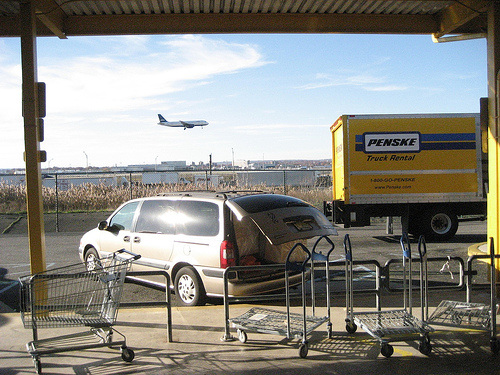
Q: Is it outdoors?
A: Yes, it is outdoors.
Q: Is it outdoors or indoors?
A: It is outdoors.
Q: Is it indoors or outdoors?
A: It is outdoors.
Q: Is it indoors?
A: No, it is outdoors.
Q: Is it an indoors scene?
A: No, it is outdoors.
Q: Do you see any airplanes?
A: Yes, there is an airplane.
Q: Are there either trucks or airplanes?
A: Yes, there is an airplane.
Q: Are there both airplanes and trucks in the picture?
A: Yes, there are both an airplane and a truck.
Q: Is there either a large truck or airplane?
A: Yes, there is a large airplane.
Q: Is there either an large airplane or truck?
A: Yes, there is a large airplane.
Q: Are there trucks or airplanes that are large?
A: Yes, the airplane is large.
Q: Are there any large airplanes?
A: Yes, there is a large airplane.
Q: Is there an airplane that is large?
A: Yes, there is an airplane that is large.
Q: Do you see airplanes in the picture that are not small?
A: Yes, there is a large airplane.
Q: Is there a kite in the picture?
A: No, there are no kites.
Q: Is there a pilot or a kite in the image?
A: No, there are no kites or pilots.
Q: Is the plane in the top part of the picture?
A: Yes, the plane is in the top of the image.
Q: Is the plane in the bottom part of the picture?
A: No, the plane is in the top of the image.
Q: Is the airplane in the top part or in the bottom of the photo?
A: The airplane is in the top of the image.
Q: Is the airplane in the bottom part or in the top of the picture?
A: The airplane is in the top of the image.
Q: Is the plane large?
A: Yes, the plane is large.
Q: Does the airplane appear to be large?
A: Yes, the airplane is large.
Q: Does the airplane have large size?
A: Yes, the airplane is large.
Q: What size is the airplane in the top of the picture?
A: The airplane is large.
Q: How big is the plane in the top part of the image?
A: The airplane is large.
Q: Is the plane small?
A: No, the plane is large.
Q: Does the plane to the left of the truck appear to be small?
A: No, the plane is large.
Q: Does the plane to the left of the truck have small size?
A: No, the plane is large.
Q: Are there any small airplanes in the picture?
A: No, there is an airplane but it is large.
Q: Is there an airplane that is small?
A: No, there is an airplane but it is large.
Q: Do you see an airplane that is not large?
A: No, there is an airplane but it is large.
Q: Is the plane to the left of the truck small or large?
A: The airplane is large.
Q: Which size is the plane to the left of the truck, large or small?
A: The airplane is large.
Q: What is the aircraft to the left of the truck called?
A: The aircraft is an airplane.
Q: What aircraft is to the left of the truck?
A: The aircraft is an airplane.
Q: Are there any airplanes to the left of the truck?
A: Yes, there is an airplane to the left of the truck.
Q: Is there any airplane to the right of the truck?
A: No, the airplane is to the left of the truck.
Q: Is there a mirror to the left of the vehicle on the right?
A: No, there is an airplane to the left of the truck.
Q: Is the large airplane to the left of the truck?
A: Yes, the airplane is to the left of the truck.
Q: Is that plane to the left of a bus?
A: No, the plane is to the left of the truck.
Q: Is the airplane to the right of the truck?
A: No, the airplane is to the left of the truck.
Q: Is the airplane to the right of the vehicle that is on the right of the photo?
A: No, the airplane is to the left of the truck.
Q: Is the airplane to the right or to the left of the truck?
A: The airplane is to the left of the truck.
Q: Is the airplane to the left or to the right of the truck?
A: The airplane is to the left of the truck.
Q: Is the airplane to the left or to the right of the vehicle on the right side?
A: The airplane is to the left of the truck.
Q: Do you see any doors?
A: Yes, there is a door.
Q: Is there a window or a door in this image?
A: Yes, there is a door.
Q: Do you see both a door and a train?
A: No, there is a door but no trains.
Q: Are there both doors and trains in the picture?
A: No, there is a door but no trains.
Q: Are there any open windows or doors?
A: Yes, there is an open door.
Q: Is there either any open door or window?
A: Yes, there is an open door.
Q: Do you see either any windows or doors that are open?
A: Yes, the door is open.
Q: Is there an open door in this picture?
A: Yes, there is an open door.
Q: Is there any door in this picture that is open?
A: Yes, there is a door that is open.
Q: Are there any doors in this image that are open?
A: Yes, there is a door that is open.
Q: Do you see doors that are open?
A: Yes, there is a door that is open.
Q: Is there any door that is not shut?
A: Yes, there is a open door.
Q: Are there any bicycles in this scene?
A: No, there are no bicycles.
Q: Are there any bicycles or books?
A: No, there are no bicycles or books.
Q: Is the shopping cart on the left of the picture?
A: Yes, the shopping cart is on the left of the image.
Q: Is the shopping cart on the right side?
A: No, the shopping cart is on the left of the image.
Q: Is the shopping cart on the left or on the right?
A: The shopping cart is on the left of the image.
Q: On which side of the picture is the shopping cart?
A: The shopping cart is on the left of the image.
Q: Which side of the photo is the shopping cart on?
A: The shopping cart is on the left of the image.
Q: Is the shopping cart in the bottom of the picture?
A: Yes, the shopping cart is in the bottom of the image.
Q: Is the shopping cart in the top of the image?
A: No, the shopping cart is in the bottom of the image.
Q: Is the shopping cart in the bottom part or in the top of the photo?
A: The shopping cart is in the bottom of the image.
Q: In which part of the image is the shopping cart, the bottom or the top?
A: The shopping cart is in the bottom of the image.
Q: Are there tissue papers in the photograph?
A: No, there are no tissue papers.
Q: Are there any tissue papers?
A: No, there are no tissue papers.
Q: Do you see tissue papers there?
A: No, there are no tissue papers.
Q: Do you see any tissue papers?
A: No, there are no tissue papers.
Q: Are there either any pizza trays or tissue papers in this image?
A: No, there are no tissue papers or pizza trays.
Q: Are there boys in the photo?
A: No, there are no boys.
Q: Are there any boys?
A: No, there are no boys.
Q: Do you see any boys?
A: No, there are no boys.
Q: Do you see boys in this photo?
A: No, there are no boys.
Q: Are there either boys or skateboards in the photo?
A: No, there are no boys or skateboards.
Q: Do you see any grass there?
A: Yes, there is grass.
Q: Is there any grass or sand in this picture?
A: Yes, there is grass.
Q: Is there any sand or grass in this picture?
A: Yes, there is grass.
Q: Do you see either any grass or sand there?
A: Yes, there is grass.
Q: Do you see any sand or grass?
A: Yes, there is grass.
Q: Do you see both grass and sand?
A: No, there is grass but no sand.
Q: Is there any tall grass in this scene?
A: Yes, there is tall grass.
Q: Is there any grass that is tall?
A: Yes, there is grass that is tall.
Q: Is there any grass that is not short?
A: Yes, there is tall grass.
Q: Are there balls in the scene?
A: No, there are no balls.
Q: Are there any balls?
A: No, there are no balls.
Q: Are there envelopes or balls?
A: No, there are no balls or envelopes.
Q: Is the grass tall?
A: Yes, the grass is tall.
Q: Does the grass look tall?
A: Yes, the grass is tall.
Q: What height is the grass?
A: The grass is tall.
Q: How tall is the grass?
A: The grass is tall.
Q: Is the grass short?
A: No, the grass is tall.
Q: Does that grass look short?
A: No, the grass is tall.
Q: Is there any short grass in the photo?
A: No, there is grass but it is tall.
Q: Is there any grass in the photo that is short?
A: No, there is grass but it is tall.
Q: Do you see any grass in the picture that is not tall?
A: No, there is grass but it is tall.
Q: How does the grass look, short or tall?
A: The grass is tall.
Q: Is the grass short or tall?
A: The grass is tall.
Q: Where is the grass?
A: The grass is in the field.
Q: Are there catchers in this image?
A: No, there are no catchers.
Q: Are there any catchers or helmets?
A: No, there are no catchers or helmets.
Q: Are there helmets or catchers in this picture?
A: No, there are no catchers or helmets.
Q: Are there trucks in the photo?
A: Yes, there is a truck.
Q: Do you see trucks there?
A: Yes, there is a truck.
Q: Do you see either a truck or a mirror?
A: Yes, there is a truck.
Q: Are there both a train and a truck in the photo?
A: No, there is a truck but no trains.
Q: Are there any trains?
A: No, there are no trains.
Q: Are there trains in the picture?
A: No, there are no trains.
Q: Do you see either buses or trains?
A: No, there are no trains or buses.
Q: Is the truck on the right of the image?
A: Yes, the truck is on the right of the image.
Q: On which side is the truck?
A: The truck is on the right of the image.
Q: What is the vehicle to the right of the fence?
A: The vehicle is a truck.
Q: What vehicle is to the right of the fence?
A: The vehicle is a truck.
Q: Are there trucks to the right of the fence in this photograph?
A: Yes, there is a truck to the right of the fence.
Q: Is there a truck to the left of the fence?
A: No, the truck is to the right of the fence.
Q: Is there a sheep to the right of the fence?
A: No, there is a truck to the right of the fence.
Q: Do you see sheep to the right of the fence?
A: No, there is a truck to the right of the fence.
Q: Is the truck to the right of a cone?
A: No, the truck is to the right of a fence.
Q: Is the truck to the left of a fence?
A: No, the truck is to the right of a fence.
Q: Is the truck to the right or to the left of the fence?
A: The truck is to the right of the fence.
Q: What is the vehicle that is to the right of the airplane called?
A: The vehicle is a truck.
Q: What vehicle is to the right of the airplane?
A: The vehicle is a truck.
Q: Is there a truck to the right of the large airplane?
A: Yes, there is a truck to the right of the plane.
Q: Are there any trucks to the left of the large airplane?
A: No, the truck is to the right of the plane.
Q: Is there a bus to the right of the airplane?
A: No, there is a truck to the right of the airplane.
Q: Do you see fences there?
A: Yes, there is a fence.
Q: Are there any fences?
A: Yes, there is a fence.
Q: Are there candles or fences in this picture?
A: Yes, there is a fence.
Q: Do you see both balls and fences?
A: No, there is a fence but no balls.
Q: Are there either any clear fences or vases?
A: Yes, there is a clear fence.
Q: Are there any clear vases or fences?
A: Yes, there is a clear fence.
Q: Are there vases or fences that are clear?
A: Yes, the fence is clear.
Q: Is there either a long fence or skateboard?
A: Yes, there is a long fence.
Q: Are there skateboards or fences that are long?
A: Yes, the fence is long.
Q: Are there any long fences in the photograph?
A: Yes, there is a long fence.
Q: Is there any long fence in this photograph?
A: Yes, there is a long fence.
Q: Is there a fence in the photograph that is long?
A: Yes, there is a fence that is long.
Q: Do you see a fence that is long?
A: Yes, there is a fence that is long.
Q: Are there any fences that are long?
A: Yes, there is a fence that is long.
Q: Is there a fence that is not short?
A: Yes, there is a long fence.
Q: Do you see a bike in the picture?
A: No, there are no bikes.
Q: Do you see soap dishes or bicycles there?
A: No, there are no bicycles or soap dishes.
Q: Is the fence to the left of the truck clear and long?
A: Yes, the fence is clear and long.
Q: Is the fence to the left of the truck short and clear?
A: No, the fence is clear but long.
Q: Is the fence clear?
A: Yes, the fence is clear.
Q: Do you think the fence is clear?
A: Yes, the fence is clear.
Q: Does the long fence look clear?
A: Yes, the fence is clear.